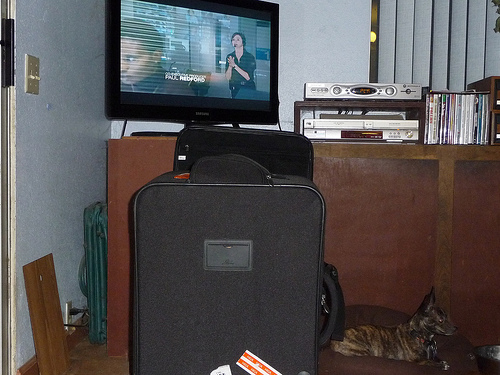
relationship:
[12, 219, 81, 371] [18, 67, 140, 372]
wood against wall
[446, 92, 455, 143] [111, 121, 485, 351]
movie standing on top of desk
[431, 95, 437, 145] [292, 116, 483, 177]
dvd on counter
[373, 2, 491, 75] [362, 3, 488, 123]
blinds are on window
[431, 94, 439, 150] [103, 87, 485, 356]
movie on desk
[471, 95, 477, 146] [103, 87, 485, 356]
movie on desk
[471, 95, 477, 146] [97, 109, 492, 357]
movie on desk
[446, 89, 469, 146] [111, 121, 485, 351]
movie on top of desk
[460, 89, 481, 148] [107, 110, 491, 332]
movie on top of desk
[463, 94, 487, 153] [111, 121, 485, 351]
movie on top of desk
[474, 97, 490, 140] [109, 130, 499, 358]
movie on top of desk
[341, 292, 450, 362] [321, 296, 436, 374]
dog laying on bed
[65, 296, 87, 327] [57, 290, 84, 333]
plug inside of outlet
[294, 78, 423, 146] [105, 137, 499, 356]
dvd on top of desk